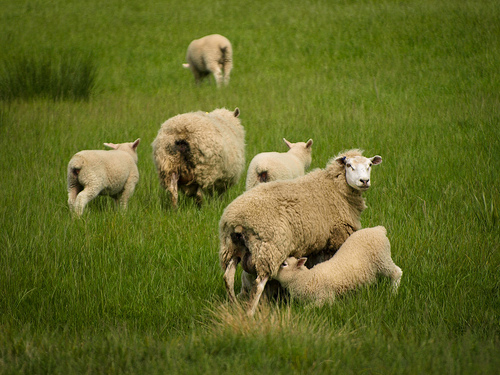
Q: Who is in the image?
A: Sheep.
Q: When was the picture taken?
A: In the day.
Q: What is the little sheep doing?
A: Nursing.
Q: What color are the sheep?
A: Off white.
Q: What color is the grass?
A: Green.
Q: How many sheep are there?
A: Six.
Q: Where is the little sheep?
A: Under its mother's belly.